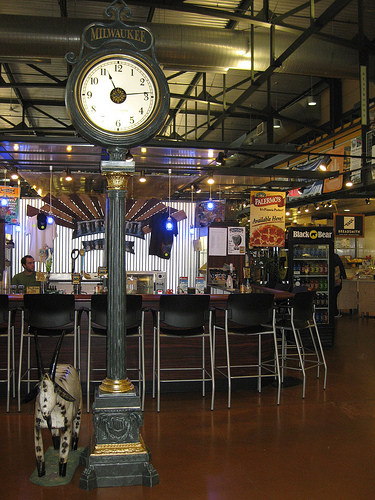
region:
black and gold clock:
[53, 17, 187, 497]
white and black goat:
[24, 353, 104, 469]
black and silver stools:
[28, 287, 362, 393]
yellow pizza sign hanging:
[237, 182, 303, 270]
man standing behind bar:
[19, 245, 64, 317]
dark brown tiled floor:
[246, 428, 362, 498]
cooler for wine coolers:
[281, 217, 358, 363]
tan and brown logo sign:
[45, 196, 185, 230]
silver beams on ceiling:
[156, 15, 295, 165]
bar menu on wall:
[206, 215, 285, 284]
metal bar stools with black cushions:
[152, 292, 316, 375]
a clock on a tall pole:
[68, 27, 164, 441]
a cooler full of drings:
[286, 228, 337, 323]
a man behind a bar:
[13, 247, 44, 313]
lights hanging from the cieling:
[156, 168, 224, 240]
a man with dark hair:
[20, 250, 39, 275]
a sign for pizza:
[240, 181, 299, 259]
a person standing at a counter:
[330, 246, 346, 312]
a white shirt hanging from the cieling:
[23, 206, 57, 257]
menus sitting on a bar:
[166, 277, 209, 297]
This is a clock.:
[65, 40, 172, 139]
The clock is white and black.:
[87, 70, 155, 136]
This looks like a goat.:
[21, 340, 87, 465]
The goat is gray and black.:
[17, 363, 98, 468]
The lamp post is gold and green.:
[88, 231, 161, 476]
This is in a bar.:
[17, 174, 312, 432]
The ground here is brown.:
[178, 400, 346, 498]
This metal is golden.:
[99, 375, 136, 392]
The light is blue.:
[150, 210, 182, 240]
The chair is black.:
[162, 290, 213, 340]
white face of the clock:
[81, 60, 157, 130]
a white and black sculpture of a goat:
[24, 346, 87, 472]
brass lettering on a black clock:
[88, 23, 157, 48]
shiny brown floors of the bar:
[194, 407, 327, 492]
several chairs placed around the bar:
[133, 294, 319, 338]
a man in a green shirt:
[12, 257, 54, 293]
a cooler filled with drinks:
[284, 226, 341, 326]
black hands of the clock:
[99, 73, 154, 98]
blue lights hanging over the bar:
[43, 203, 217, 240]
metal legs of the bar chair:
[138, 341, 330, 402]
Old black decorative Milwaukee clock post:
[69, 3, 175, 492]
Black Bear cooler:
[273, 225, 336, 343]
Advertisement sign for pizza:
[248, 190, 283, 245]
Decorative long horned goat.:
[25, 332, 85, 484]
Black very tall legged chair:
[150, 294, 215, 411]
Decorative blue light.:
[162, 210, 171, 229]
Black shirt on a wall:
[146, 210, 176, 255]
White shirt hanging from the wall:
[21, 211, 55, 256]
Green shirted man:
[11, 251, 44, 288]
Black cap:
[34, 212, 46, 228]